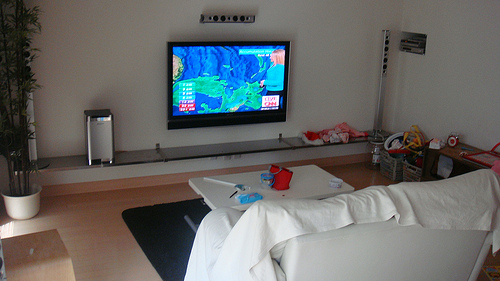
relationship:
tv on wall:
[165, 39, 292, 130] [0, 2, 499, 188]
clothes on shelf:
[299, 121, 369, 148] [17, 127, 389, 175]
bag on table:
[269, 164, 293, 189] [189, 161, 355, 215]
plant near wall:
[0, 2, 44, 198] [0, 2, 499, 188]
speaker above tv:
[200, 12, 256, 24] [165, 39, 292, 130]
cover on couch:
[182, 169, 499, 280] [184, 165, 498, 280]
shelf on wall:
[17, 127, 389, 175] [0, 2, 499, 188]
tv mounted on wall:
[165, 39, 292, 130] [0, 2, 499, 188]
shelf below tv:
[17, 127, 389, 175] [165, 39, 292, 130]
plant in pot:
[0, 2, 44, 198] [0, 180, 44, 221]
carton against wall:
[377, 149, 405, 180] [0, 2, 499, 188]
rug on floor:
[122, 197, 211, 280] [1, 157, 498, 279]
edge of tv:
[163, 109, 287, 130] [165, 39, 292, 130]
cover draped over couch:
[182, 169, 499, 280] [184, 165, 498, 280]